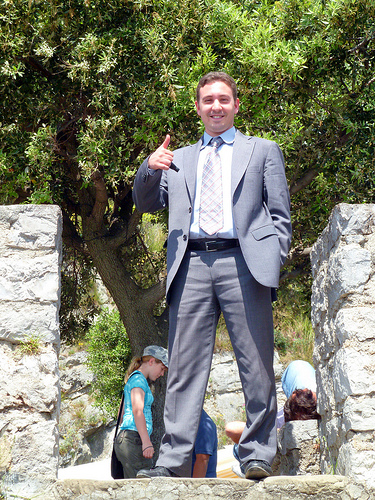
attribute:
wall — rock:
[0, 203, 373, 498]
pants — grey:
[152, 237, 280, 472]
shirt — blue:
[190, 126, 237, 239]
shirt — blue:
[120, 371, 156, 437]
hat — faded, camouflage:
[139, 345, 168, 369]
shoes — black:
[133, 457, 271, 480]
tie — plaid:
[200, 136, 225, 235]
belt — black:
[186, 237, 240, 253]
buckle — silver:
[204, 239, 216, 251]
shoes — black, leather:
[130, 462, 275, 481]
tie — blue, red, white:
[197, 137, 223, 235]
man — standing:
[131, 70, 293, 477]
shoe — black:
[237, 457, 277, 477]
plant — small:
[16, 333, 47, 358]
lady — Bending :
[279, 358, 324, 434]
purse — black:
[111, 391, 123, 477]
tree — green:
[0, 1, 375, 467]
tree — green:
[2, 23, 361, 244]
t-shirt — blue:
[121, 369, 153, 435]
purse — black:
[110, 368, 140, 480]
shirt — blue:
[118, 369, 153, 433]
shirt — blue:
[190, 409, 216, 478]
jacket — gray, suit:
[131, 127, 293, 304]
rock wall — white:
[0, 198, 375, 499]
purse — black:
[94, 393, 127, 491]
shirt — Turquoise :
[117, 367, 155, 435]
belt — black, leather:
[191, 240, 237, 249]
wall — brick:
[0, 204, 57, 497]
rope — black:
[24, 23, 83, 183]